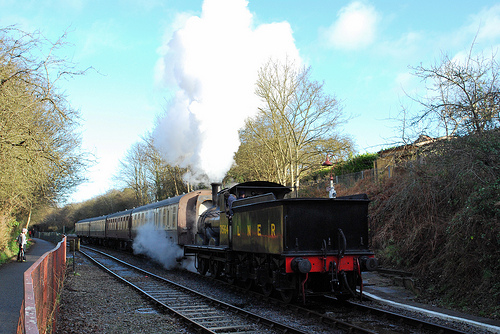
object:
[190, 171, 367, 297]
front car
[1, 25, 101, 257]
tree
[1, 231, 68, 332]
side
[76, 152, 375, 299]
train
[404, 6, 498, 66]
clouds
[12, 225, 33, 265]
person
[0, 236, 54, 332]
sidewalk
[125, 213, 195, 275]
smoke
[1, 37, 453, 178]
sky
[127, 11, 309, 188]
smoke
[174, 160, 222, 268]
engine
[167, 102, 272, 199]
white smoke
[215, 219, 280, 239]
writing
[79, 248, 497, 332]
track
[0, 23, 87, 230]
leaves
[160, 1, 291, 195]
steam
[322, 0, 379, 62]
cloud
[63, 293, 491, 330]
ground